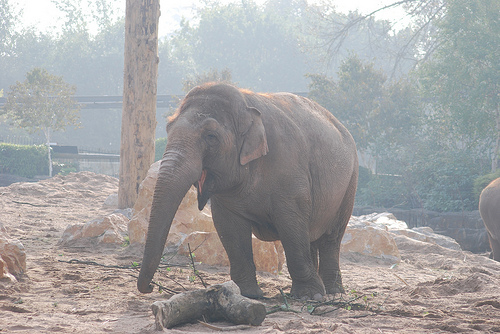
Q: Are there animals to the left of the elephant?
A: Yes, there is an animal to the left of the elephant.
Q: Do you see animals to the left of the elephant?
A: Yes, there is an animal to the left of the elephant.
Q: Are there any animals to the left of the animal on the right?
A: Yes, there is an animal to the left of the elephant.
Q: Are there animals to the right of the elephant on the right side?
A: No, the animal is to the left of the elephant.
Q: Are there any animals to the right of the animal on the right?
A: No, the animal is to the left of the elephant.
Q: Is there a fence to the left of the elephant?
A: No, there is an animal to the left of the elephant.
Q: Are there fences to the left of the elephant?
A: No, there is an animal to the left of the elephant.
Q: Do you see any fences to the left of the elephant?
A: No, there is an animal to the left of the elephant.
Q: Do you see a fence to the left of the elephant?
A: No, there is an animal to the left of the elephant.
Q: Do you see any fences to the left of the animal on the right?
A: No, there is an animal to the left of the elephant.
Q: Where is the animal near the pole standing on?
A: The animal is standing on the ground.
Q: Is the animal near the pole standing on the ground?
A: Yes, the animal is standing on the ground.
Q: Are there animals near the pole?
A: Yes, there is an animal near the pole.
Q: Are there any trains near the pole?
A: No, there is an animal near the pole.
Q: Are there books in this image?
A: No, there are no books.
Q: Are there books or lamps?
A: No, there are no books or lamps.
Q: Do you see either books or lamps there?
A: No, there are no books or lamps.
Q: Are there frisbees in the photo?
A: No, there are no frisbees.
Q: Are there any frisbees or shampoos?
A: No, there are no frisbees or shampoos.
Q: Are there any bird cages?
A: No, there are no bird cages.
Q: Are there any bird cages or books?
A: No, there are no bird cages or books.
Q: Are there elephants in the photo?
A: Yes, there is an elephant.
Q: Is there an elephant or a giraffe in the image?
A: Yes, there is an elephant.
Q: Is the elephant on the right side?
A: Yes, the elephant is on the right of the image.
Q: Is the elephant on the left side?
A: No, the elephant is on the right of the image.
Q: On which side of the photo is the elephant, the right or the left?
A: The elephant is on the right of the image.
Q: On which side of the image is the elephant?
A: The elephant is on the right of the image.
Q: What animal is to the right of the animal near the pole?
A: The animal is an elephant.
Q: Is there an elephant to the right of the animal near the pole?
A: Yes, there is an elephant to the right of the animal.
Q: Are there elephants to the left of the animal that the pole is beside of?
A: No, the elephant is to the right of the animal.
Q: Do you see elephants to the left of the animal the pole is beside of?
A: No, the elephant is to the right of the animal.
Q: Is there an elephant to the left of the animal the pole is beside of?
A: No, the elephant is to the right of the animal.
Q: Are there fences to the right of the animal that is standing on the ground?
A: No, there is an elephant to the right of the animal.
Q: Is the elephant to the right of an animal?
A: Yes, the elephant is to the right of an animal.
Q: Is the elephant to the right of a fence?
A: No, the elephant is to the right of an animal.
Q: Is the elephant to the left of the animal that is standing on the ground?
A: No, the elephant is to the right of the animal.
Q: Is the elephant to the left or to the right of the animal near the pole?
A: The elephant is to the right of the animal.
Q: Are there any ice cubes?
A: No, there are no ice cubes.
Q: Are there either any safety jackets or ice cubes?
A: No, there are no ice cubes or safety jackets.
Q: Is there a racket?
A: No, there are no rackets.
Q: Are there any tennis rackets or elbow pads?
A: No, there are no tennis rackets or elbow pads.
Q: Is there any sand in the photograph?
A: Yes, there is sand.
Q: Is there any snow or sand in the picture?
A: Yes, there is sand.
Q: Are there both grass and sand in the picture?
A: No, there is sand but no grass.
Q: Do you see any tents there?
A: No, there are no tents.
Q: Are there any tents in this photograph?
A: No, there are no tents.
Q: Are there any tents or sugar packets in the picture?
A: No, there are no tents or sugar packets.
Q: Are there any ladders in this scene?
A: No, there are no ladders.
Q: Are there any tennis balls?
A: No, there are no tennis balls.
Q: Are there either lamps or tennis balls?
A: No, there are no tennis balls or lamps.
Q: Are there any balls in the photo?
A: No, there are no balls.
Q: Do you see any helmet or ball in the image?
A: No, there are no balls or helmets.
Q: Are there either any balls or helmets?
A: No, there are no balls or helmets.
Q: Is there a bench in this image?
A: No, there are no benches.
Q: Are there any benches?
A: No, there are no benches.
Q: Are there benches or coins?
A: No, there are no benches or coins.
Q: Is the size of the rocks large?
A: Yes, the rocks are large.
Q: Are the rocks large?
A: Yes, the rocks are large.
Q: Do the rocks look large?
A: Yes, the rocks are large.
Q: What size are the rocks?
A: The rocks are large.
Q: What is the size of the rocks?
A: The rocks are large.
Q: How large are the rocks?
A: The rocks are large.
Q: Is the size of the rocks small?
A: No, the rocks are large.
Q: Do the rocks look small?
A: No, the rocks are large.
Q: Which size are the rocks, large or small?
A: The rocks are large.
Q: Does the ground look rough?
A: Yes, the ground is rough.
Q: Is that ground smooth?
A: No, the ground is rough.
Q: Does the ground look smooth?
A: No, the ground is rough.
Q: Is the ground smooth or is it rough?
A: The ground is rough.